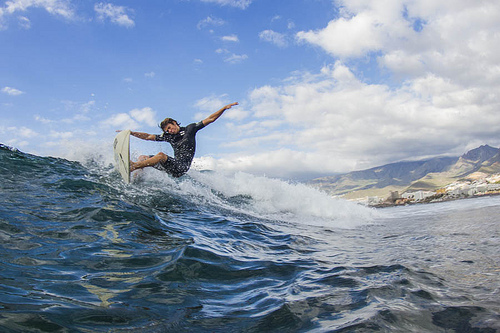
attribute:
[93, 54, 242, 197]
man — surfing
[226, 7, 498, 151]
clouds — white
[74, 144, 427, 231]
foam — white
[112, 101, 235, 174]
man — wearing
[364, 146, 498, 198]
mountain — high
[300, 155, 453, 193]
mountain — high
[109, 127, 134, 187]
surfboard — white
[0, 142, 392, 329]
waves — blue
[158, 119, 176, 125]
hair — brown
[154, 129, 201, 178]
wetsuit — black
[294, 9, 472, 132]
clouds — white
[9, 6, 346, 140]
sky — blue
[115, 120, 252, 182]
navy blue — surfboarding suit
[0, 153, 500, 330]
water — blue